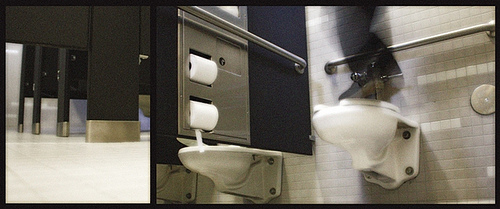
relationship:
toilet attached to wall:
[305, 95, 425, 192] [161, 8, 492, 195]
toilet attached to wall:
[177, 141, 288, 203] [161, 8, 492, 195]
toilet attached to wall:
[159, 168, 196, 203] [193, 7, 494, 202]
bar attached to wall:
[320, 17, 495, 74] [271, 11, 493, 203]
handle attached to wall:
[185, 7, 307, 73] [193, 7, 494, 202]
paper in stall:
[183, 50, 222, 90] [181, 7, 320, 197]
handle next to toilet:
[185, 7, 307, 73] [308, 97, 420, 190]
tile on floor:
[23, 162, 142, 198] [13, 135, 150, 207]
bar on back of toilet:
[320, 17, 495, 74] [311, 97, 418, 184]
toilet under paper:
[177, 141, 288, 203] [168, 96, 226, 143]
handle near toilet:
[185, 7, 307, 73] [265, 56, 480, 140]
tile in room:
[3, 40, 148, 207] [3, 5, 148, 205]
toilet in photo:
[177, 141, 288, 203] [158, 1, 494, 203]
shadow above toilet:
[326, 5, 383, 57] [305, 95, 425, 192]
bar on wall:
[320, 17, 495, 74] [309, 8, 495, 206]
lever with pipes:
[382, 72, 404, 80] [350, 54, 405, 98]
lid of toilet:
[307, 92, 402, 118] [318, 94, 426, 184]